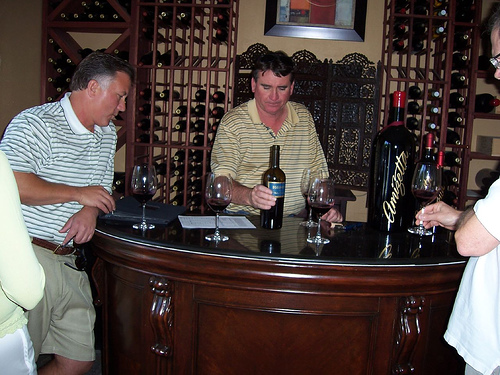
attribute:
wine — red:
[259, 141, 288, 233]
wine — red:
[368, 90, 415, 235]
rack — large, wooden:
[135, 0, 240, 179]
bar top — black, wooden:
[107, 199, 455, 271]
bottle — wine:
[444, 110, 464, 125]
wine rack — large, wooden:
[42, 4, 128, 207]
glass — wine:
[408, 167, 440, 236]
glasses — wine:
[286, 176, 377, 253]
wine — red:
[392, 8, 454, 185]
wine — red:
[136, 6, 228, 208]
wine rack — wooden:
[41, 17, 143, 203]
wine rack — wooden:
[137, 13, 241, 205]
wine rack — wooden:
[367, 13, 483, 221]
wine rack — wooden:
[465, 35, 497, 212]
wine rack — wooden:
[133, 0, 232, 217]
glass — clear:
[395, 147, 455, 239]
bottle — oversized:
[345, 87, 435, 251]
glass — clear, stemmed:
[202, 170, 235, 243]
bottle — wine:
[447, 93, 467, 105]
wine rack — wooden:
[371, 0, 499, 250]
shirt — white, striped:
[0, 92, 118, 245]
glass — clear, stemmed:
[309, 179, 335, 243]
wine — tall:
[309, 198, 334, 215]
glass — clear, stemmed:
[116, 146, 175, 235]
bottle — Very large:
[368, 90, 416, 235]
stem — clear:
[315, 212, 323, 238]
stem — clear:
[212, 208, 221, 237]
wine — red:
[410, 188, 440, 206]